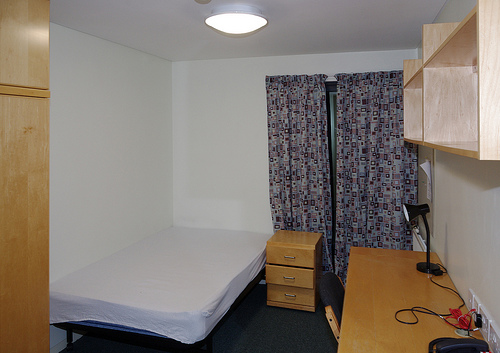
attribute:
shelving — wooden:
[391, 1, 498, 161]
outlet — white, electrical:
[462, 293, 497, 343]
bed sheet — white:
[47, 225, 273, 345]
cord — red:
[444, 300, 481, 333]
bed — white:
[30, 214, 294, 350]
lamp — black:
[377, 192, 449, 296]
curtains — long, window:
[261, 67, 423, 285]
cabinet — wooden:
[393, 9, 477, 152]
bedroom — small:
[1, 2, 498, 350]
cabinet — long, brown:
[2, 1, 47, 351]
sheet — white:
[149, 217, 201, 324]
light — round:
[196, 10, 291, 59]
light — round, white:
[200, 4, 270, 41]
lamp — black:
[397, 196, 448, 278]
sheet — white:
[126, 211, 223, 312]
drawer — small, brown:
[249, 185, 353, 351]